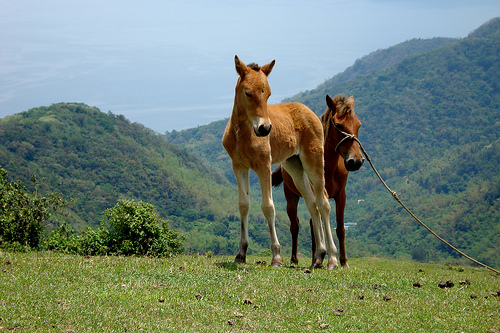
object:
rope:
[336, 130, 498, 272]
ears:
[232, 55, 248, 76]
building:
[342, 222, 358, 230]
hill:
[363, 19, 499, 266]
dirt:
[412, 262, 488, 304]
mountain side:
[6, 96, 220, 220]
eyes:
[244, 91, 254, 98]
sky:
[0, 5, 499, 123]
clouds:
[0, 0, 496, 120]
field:
[1, 252, 494, 333]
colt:
[219, 57, 340, 272]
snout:
[260, 115, 270, 130]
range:
[5, 17, 500, 284]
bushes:
[0, 165, 180, 256]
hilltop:
[0, 99, 164, 163]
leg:
[230, 159, 254, 264]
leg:
[253, 162, 283, 269]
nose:
[263, 122, 272, 132]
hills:
[0, 99, 333, 266]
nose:
[354, 155, 363, 164]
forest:
[219, 13, 497, 273]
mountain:
[0, 2, 497, 264]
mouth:
[346, 158, 366, 172]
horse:
[270, 91, 368, 264]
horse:
[209, 53, 330, 268]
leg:
[284, 164, 327, 270]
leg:
[300, 149, 341, 272]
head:
[231, 54, 278, 138]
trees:
[347, 19, 500, 266]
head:
[325, 94, 366, 172]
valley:
[281, 189, 427, 269]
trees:
[0, 133, 167, 191]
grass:
[0, 248, 498, 333]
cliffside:
[0, 247, 179, 294]